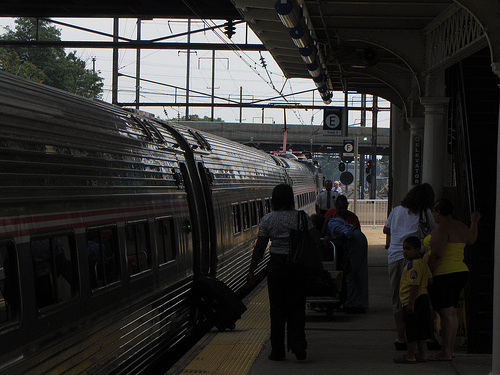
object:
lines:
[180, 0, 283, 94]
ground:
[446, 182, 459, 202]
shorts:
[400, 294, 432, 344]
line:
[242, 344, 267, 374]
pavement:
[165, 224, 463, 373]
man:
[314, 179, 341, 215]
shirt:
[257, 209, 315, 255]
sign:
[342, 138, 354, 157]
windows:
[0, 237, 25, 331]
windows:
[230, 202, 242, 236]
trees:
[42, 52, 105, 100]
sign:
[323, 106, 345, 136]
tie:
[325, 190, 331, 210]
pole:
[276, 4, 334, 104]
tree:
[0, 48, 47, 83]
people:
[307, 212, 368, 314]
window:
[32, 227, 83, 314]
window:
[87, 222, 123, 293]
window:
[123, 219, 153, 278]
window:
[156, 215, 180, 268]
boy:
[392, 236, 434, 363]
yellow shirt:
[399, 258, 434, 308]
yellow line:
[180, 287, 272, 374]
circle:
[325, 113, 340, 129]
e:
[329, 115, 337, 126]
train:
[0, 83, 326, 374]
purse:
[287, 210, 324, 272]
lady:
[246, 183, 322, 361]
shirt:
[421, 234, 469, 276]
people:
[325, 194, 362, 304]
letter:
[346, 144, 351, 151]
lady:
[423, 197, 482, 360]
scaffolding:
[0, 17, 389, 199]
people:
[383, 182, 438, 350]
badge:
[331, 194, 336, 200]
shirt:
[313, 189, 341, 210]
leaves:
[11, 53, 29, 69]